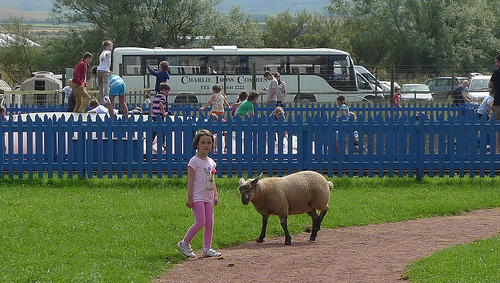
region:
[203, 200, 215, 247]
the leg of a girl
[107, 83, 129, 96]
a girl's blue shorts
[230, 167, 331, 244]
a brown animal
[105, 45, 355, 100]
a white bus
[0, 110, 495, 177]
a long blue picket fence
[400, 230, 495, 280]
a section of green grass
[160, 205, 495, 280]
a brown dirt walkway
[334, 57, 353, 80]
the window of a bus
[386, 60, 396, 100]
a wooden pole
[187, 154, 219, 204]
a girl's pink short sleeve shirt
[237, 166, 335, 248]
sheep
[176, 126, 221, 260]
little girl with pink pants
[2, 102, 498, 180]
blue picket fence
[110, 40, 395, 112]
large white bus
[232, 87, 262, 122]
person with bright green shirt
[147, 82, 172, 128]
person with red and white striped shirt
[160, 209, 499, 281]
dirt path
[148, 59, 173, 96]
person with dark blue shirt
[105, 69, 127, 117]
person in light blue shorts bending over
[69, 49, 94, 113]
person with red shirt and tan khakis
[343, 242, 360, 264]
part of a ground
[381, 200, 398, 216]
edge of a path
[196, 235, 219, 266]
prt of a shoe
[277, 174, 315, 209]
part of a stomach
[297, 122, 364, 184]
part of a fence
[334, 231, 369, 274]
part of a ground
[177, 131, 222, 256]
the little girl is looking straigh on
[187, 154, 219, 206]
the little girl is wearing a short sleeve shirt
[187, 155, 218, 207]
the shirt is pink in color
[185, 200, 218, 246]
the little girl is wearing pants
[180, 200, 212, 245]
the pants are pink in color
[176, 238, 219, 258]
the little girl is wearing sneakers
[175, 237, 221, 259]
the sneakers are white in color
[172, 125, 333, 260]
the little girl is standing next to a lamb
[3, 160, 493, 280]
the field is full of grass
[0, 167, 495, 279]
the grass is green in color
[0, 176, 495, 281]
a curving dirt path in the midst of a grassy area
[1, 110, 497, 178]
a blue picket fence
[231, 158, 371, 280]
sheep standing on dirt path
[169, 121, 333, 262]
young girl standing near sheep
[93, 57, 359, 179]
people standing behind fence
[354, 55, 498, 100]
cars parked behind a fence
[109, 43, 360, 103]
a black and white bus parked just behind a fence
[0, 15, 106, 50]
fields in the distance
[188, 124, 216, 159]
young girl has short dark hair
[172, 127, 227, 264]
girl's right leg is slightly bent back